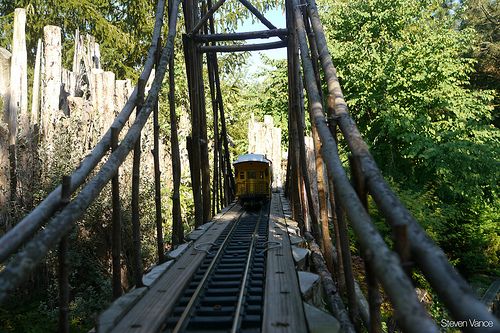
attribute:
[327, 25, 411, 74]
trees — shady, green, lots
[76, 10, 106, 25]
leaves — green, brown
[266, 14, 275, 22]
sky — clear, blue, patchy, bright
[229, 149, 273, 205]
train — yellow, one car, moving, crossing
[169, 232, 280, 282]
bridge — wooden, dark, suspension, narrow, shaded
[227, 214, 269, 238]
tracks — metal, dark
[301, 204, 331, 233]
trunks — light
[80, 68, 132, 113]
wall — large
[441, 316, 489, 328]
watermark — steven vance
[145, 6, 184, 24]
rod — steel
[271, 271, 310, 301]
plank — wooden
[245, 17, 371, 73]
forest — summer